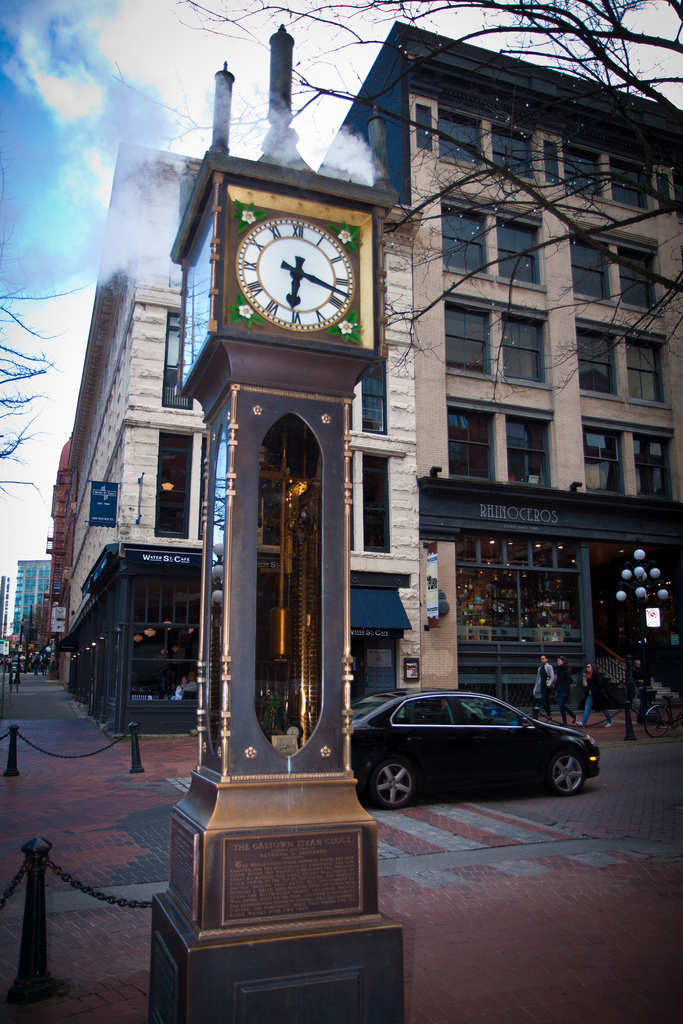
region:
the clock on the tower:
[147, 21, 407, 1021]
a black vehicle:
[351, 682, 600, 802]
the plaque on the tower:
[165, 811, 372, 932]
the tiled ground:
[12, 727, 680, 1018]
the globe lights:
[611, 542, 670, 740]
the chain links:
[2, 717, 152, 915]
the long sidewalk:
[14, 658, 102, 737]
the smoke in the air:
[104, 88, 383, 272]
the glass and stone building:
[12, 551, 51, 630]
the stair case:
[599, 646, 672, 718]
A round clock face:
[235, 214, 359, 318]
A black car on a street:
[349, 683, 596, 797]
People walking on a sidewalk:
[536, 653, 614, 725]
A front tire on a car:
[550, 745, 584, 793]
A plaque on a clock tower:
[227, 827, 372, 919]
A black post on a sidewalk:
[18, 837, 61, 1000]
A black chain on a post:
[51, 859, 159, 908]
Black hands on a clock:
[278, 257, 350, 309]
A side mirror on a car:
[518, 711, 533, 727]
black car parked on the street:
[333, 670, 599, 808]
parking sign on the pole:
[639, 600, 668, 633]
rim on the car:
[555, 751, 585, 796]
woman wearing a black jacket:
[578, 665, 608, 706]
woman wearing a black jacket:
[553, 661, 580, 693]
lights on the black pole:
[609, 538, 682, 604]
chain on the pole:
[41, 852, 164, 924]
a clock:
[238, 211, 365, 329]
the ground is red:
[492, 922, 592, 1003]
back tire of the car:
[369, 763, 417, 808]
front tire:
[552, 754, 584, 795]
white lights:
[609, 553, 665, 606]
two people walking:
[534, 649, 576, 718]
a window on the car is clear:
[455, 700, 504, 727]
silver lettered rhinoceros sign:
[477, 503, 558, 521]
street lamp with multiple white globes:
[617, 548, 668, 740]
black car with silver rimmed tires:
[351, 689, 599, 806]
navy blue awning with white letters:
[348, 585, 411, 636]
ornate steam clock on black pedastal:
[147, 24, 405, 1022]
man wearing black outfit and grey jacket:
[532, 654, 555, 720]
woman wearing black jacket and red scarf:
[577, 660, 611, 726]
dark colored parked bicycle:
[643, 692, 682, 736]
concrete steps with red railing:
[594, 635, 678, 697]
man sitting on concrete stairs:
[634, 658, 642, 685]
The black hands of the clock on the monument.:
[274, 244, 344, 317]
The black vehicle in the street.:
[351, 683, 603, 808]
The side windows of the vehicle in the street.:
[394, 702, 523, 729]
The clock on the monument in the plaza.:
[239, 202, 371, 340]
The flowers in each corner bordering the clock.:
[229, 199, 371, 346]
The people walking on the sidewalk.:
[539, 648, 658, 732]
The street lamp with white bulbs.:
[600, 530, 673, 750]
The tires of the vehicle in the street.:
[363, 755, 594, 804]